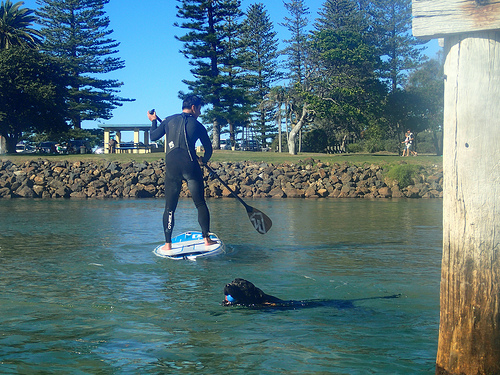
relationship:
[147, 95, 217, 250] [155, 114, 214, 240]
man wearing wet suit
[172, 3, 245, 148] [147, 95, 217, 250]
tree behind man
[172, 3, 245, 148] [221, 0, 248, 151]
tree next to tree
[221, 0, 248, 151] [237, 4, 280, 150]
tree next to tree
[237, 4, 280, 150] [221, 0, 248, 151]
tree next to tree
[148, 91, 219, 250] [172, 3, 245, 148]
man in from of tree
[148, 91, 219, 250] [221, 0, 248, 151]
man in front of tree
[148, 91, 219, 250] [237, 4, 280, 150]
man in front of tree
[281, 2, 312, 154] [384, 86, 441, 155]
tree next to tree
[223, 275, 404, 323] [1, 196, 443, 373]
dog in water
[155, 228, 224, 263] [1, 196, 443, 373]
board in water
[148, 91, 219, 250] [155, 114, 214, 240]
man wearing wet suit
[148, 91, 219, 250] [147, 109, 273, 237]
man holding paddle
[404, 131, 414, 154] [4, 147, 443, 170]
person on grass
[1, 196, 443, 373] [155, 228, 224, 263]
water beneath board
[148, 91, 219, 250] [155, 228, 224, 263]
man paddling board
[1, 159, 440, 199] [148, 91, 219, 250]
rocks behind man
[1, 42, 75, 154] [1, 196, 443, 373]
tree near water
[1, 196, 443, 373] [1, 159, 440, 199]
water next to rocks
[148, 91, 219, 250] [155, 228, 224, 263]
man on board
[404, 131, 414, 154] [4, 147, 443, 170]
person walking on grass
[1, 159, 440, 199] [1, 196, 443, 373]
rocks near water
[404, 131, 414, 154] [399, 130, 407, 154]
person walking next to person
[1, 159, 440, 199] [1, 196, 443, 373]
rocks next to water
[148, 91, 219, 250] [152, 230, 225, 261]
man standing on board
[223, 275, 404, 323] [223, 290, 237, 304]
dog holding blue ball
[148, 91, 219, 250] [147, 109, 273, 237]
man using paddle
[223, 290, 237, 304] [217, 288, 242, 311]
blue ball in mouth